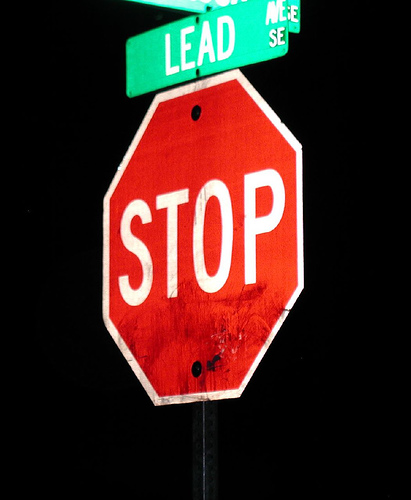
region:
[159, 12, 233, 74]
white letters on a street sign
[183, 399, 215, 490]
a metal post supporting a sign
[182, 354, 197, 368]
a bolt attaching a sign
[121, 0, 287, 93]
a green street sign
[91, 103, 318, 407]
a red stop sign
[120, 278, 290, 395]
dirt smears on a stop sign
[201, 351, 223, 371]
a dark spot on a stop sign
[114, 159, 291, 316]
white letters on a stop sign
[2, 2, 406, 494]
a dark night sky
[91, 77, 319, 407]
white trim around a stop sign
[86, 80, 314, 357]
stop sign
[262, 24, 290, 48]
Lead street sign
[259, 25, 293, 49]
direction of avenue on street sign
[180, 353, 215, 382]
grommet to hold stop sign on post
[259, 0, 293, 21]
type of street is avenue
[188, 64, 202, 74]
grommet holder for street sign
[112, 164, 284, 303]
the word "stop"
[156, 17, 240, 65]
the word "Lead"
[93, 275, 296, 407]
dirt on bottom of a stop sign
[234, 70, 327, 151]
ripples in the edges of a stop sign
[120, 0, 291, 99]
The street sign that is fully readable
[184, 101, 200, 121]
The circle on the top of the stop sign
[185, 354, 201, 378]
The circle on the bottom of the stop sign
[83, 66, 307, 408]
The red stop sign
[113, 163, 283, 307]
The white letters on the sign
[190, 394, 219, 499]
The pole holding the sign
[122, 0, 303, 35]
The street sign only partially shown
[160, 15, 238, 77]
The word 'lead'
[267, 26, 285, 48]
The letters 'se' on the street sign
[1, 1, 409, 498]
The black background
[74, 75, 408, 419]
the signboard is octagon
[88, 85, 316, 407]
Red stop sign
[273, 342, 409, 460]
Taken at dark time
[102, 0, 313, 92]
Green street sign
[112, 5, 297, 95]
Sign that reads LEAD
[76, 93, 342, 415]
Red sign reflecting light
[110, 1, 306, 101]
Green street sign reflecting light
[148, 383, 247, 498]
Street sign pole at night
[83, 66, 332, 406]
Dirty street sign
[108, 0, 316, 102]
Reflecting street sign shining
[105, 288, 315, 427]
Black marks on stop sign